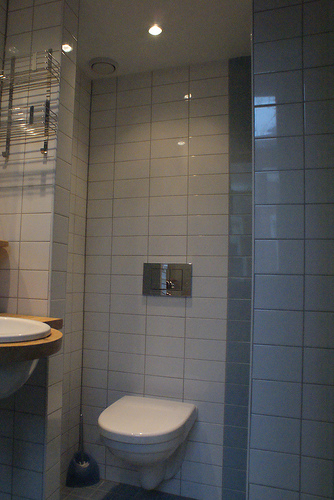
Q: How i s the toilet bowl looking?
A: White.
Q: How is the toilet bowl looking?
A: White.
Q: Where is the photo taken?
A: Bathroom.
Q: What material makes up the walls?
A: White tiles.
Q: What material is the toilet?
A: Porcelain.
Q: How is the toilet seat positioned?
A: Down.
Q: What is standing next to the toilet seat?
A: A plunger.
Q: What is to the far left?
A: A sink.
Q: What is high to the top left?
A: A towel rack.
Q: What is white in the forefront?
A: A toilet.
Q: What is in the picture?
A: A commode.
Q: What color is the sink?
A: White.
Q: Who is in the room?
A: Nobody.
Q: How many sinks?
A: One.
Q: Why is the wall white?
A: To match the room.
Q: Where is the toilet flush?
A: Above the toilet.